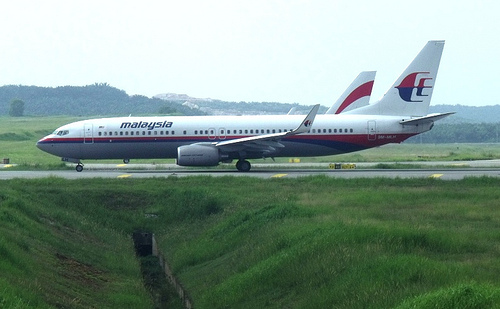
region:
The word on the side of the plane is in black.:
[119, 117, 178, 127]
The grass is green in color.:
[291, 272, 381, 303]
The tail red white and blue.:
[392, 33, 450, 113]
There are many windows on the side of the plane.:
[94, 128, 359, 135]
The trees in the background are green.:
[33, 87, 107, 109]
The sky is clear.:
[54, 20, 174, 65]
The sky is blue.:
[395, 7, 470, 35]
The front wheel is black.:
[71, 163, 87, 173]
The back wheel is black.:
[233, 155, 256, 175]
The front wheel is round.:
[70, 164, 90, 174]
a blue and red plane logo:
[394, 69, 430, 103]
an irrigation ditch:
[136, 230, 180, 307]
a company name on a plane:
[117, 115, 173, 131]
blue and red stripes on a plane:
[39, 134, 354, 153]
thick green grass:
[234, 187, 436, 285]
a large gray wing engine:
[176, 140, 239, 172]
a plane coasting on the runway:
[28, 32, 464, 193]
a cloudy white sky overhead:
[18, 2, 448, 90]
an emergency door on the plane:
[369, 115, 382, 143]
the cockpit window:
[48, 126, 73, 136]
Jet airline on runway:
[37, 39, 455, 171]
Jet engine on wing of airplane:
[172, 147, 222, 167]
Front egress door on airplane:
[81, 123, 95, 147]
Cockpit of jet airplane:
[52, 127, 72, 139]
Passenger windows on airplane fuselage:
[92, 127, 355, 137]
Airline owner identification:
[117, 119, 172, 131]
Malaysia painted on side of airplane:
[118, 118, 172, 131]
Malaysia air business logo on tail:
[390, 70, 434, 104]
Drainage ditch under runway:
[130, 231, 191, 308]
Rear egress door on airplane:
[365, 117, 377, 141]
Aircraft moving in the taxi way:
[36, 37, 460, 174]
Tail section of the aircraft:
[340, 37, 455, 149]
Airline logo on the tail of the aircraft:
[392, 69, 436, 104]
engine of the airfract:
[172, 144, 227, 168]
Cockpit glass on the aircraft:
[49, 128, 70, 135]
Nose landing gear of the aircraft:
[74, 157, 85, 173]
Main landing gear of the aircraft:
[233, 157, 252, 172]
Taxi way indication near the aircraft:
[325, 162, 356, 170]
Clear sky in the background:
[2, 0, 492, 105]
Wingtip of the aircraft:
[292, 103, 322, 134]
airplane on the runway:
[35, 37, 460, 176]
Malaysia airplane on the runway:
[30, 35, 458, 178]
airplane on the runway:
[0, 3, 499, 303]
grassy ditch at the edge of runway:
[9, 160, 330, 307]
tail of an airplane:
[321, 31, 463, 178]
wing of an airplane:
[163, 90, 360, 207]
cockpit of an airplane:
[33, 104, 111, 174]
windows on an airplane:
[81, 113, 363, 141]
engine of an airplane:
[167, 122, 241, 180]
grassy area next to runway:
[180, 157, 493, 292]